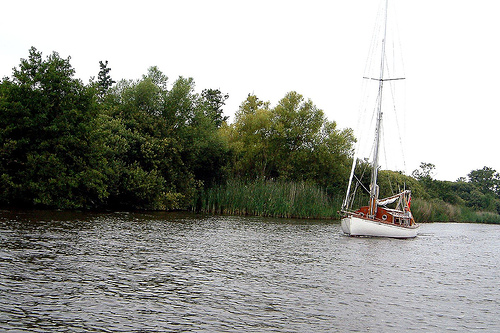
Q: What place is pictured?
A: It is a river.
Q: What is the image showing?
A: It is showing a river.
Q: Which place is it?
A: It is a river.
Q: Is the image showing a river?
A: Yes, it is showing a river.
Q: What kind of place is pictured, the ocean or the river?
A: It is the river.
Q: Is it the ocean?
A: No, it is the river.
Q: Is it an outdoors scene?
A: Yes, it is outdoors.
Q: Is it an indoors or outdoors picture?
A: It is outdoors.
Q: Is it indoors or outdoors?
A: It is outdoors.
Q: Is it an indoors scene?
A: No, it is outdoors.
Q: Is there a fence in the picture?
A: No, there are no fences.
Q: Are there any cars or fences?
A: No, there are no fences or cars.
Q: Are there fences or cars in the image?
A: No, there are no fences or cars.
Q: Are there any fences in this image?
A: No, there are no fences.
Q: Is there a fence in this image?
A: No, there are no fences.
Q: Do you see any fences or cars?
A: No, there are no fences or cars.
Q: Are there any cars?
A: No, there are no cars.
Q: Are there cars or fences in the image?
A: No, there are no cars or fences.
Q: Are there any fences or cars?
A: No, there are no cars or fences.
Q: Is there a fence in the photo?
A: No, there are no fences.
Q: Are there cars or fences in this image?
A: No, there are no fences or cars.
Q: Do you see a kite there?
A: No, there are no kites.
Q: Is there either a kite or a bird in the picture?
A: No, there are no kites or birds.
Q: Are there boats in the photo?
A: Yes, there is a boat.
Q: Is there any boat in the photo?
A: Yes, there is a boat.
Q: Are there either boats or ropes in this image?
A: Yes, there is a boat.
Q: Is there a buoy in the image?
A: No, there are no buoys.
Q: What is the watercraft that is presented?
A: The watercraft is a boat.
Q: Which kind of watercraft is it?
A: The watercraft is a boat.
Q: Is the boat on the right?
A: Yes, the boat is on the right of the image.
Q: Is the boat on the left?
A: No, the boat is on the right of the image.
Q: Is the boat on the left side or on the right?
A: The boat is on the right of the image.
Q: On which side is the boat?
A: The boat is on the right of the image.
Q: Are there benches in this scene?
A: No, there are no benches.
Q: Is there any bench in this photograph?
A: No, there are no benches.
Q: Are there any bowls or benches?
A: No, there are no benches or bowls.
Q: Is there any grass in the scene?
A: Yes, there is grass.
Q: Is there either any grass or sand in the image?
A: Yes, there is grass.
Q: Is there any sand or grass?
A: Yes, there is grass.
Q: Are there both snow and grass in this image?
A: No, there is grass but no snow.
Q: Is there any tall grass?
A: Yes, there is tall grass.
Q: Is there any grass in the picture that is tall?
A: Yes, there is grass that is tall.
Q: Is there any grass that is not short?
A: Yes, there is tall grass.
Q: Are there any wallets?
A: No, there are no wallets.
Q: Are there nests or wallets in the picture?
A: No, there are no wallets or nests.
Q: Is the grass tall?
A: Yes, the grass is tall.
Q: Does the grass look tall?
A: Yes, the grass is tall.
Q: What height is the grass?
A: The grass is tall.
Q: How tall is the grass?
A: The grass is tall.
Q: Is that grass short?
A: No, the grass is tall.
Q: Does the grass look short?
A: No, the grass is tall.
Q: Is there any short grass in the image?
A: No, there is grass but it is tall.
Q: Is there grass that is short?
A: No, there is grass but it is tall.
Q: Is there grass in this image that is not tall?
A: No, there is grass but it is tall.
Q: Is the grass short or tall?
A: The grass is tall.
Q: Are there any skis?
A: No, there are no skis.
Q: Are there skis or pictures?
A: No, there are no skis or pictures.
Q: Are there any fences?
A: No, there are no fences.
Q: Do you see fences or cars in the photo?
A: No, there are no fences or cars.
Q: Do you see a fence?
A: No, there are no fences.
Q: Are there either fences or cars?
A: No, there are no fences or cars.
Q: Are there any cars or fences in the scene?
A: No, there are no fences or cars.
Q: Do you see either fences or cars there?
A: No, there are no fences or cars.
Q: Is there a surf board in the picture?
A: No, there are no surfboards.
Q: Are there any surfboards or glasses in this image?
A: No, there are no surfboards or glasses.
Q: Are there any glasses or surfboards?
A: No, there are no surfboards or glasses.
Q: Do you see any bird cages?
A: No, there are no bird cages.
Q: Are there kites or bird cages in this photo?
A: No, there are no bird cages or kites.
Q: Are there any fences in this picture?
A: No, there are no fences.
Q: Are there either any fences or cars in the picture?
A: No, there are no fences or cars.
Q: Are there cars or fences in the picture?
A: No, there are no fences or cars.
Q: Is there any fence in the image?
A: No, there are no fences.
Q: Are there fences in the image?
A: No, there are no fences.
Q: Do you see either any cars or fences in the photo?
A: No, there are no fences or cars.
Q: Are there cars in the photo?
A: No, there are no cars.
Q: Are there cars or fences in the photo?
A: No, there are no cars or fences.